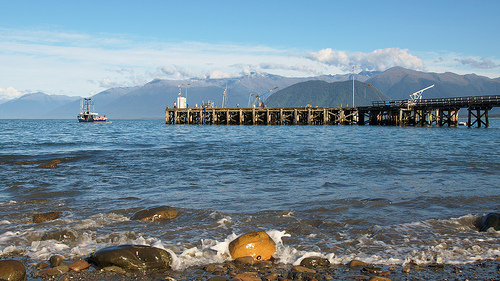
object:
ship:
[77, 96, 112, 123]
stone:
[88, 243, 173, 272]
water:
[0, 115, 499, 271]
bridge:
[162, 95, 499, 128]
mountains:
[364, 66, 499, 114]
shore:
[1, 196, 500, 280]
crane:
[409, 84, 434, 102]